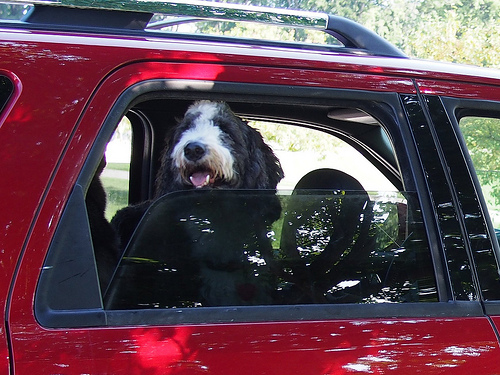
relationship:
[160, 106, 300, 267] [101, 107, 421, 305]
dog looking out of window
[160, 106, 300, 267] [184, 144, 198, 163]
dog has nose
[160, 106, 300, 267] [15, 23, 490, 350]
dog sitting in car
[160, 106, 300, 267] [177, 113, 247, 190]
dog has head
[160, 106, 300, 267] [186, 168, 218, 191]
dog has mouth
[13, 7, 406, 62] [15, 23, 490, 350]
rack on top of car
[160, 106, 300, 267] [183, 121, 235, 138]
dog has eyes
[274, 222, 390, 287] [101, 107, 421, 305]
reflection in window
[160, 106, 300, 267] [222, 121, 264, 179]
dog has fur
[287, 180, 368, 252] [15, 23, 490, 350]
headrest inside of car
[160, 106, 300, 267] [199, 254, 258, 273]
dog wearing collar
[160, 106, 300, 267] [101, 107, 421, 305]
dog peeking out of window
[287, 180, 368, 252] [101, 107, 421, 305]
headrest seen through window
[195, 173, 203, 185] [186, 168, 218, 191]
tongue in mouth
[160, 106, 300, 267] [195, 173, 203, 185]
dog has tongue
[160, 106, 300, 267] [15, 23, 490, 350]
dog inside car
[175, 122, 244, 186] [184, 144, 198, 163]
face has nose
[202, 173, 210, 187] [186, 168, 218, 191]
teeth inside of mouth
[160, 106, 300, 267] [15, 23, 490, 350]
dog standing in car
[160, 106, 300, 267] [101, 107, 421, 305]
dog inside window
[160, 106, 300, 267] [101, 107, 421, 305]
dog hanging out of window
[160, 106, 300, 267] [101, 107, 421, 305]
dog next to window